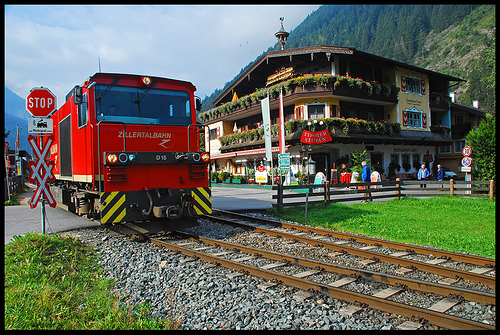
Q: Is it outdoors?
A: Yes, it is outdoors.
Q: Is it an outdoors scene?
A: Yes, it is outdoors.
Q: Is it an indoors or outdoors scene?
A: It is outdoors.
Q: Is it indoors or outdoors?
A: It is outdoors.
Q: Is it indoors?
A: No, it is outdoors.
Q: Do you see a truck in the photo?
A: No, there are no trucks.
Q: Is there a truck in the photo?
A: No, there are no trucks.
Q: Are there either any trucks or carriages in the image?
A: No, there are no trucks or carriages.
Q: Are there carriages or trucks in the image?
A: No, there are no trucks or carriages.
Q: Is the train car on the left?
A: Yes, the train car is on the left of the image.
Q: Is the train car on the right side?
A: No, the train car is on the left of the image.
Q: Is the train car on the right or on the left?
A: The train car is on the left of the image.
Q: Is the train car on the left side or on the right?
A: The train car is on the left of the image.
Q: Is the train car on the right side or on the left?
A: The train car is on the left of the image.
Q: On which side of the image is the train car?
A: The train car is on the left of the image.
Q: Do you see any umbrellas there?
A: No, there are no umbrellas.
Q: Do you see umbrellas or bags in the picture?
A: No, there are no umbrellas or bags.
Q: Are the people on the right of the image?
A: Yes, the people are on the right of the image.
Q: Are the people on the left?
A: No, the people are on the right of the image.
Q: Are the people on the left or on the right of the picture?
A: The people are on the right of the image.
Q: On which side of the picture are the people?
A: The people are on the right of the image.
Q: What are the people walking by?
A: The people are walking by the entrance.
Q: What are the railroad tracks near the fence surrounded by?
A: The railroad tracks are surrounded by the rocks.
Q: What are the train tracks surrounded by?
A: The railroad tracks are surrounded by the rocks.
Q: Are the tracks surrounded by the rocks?
A: Yes, the tracks are surrounded by the rocks.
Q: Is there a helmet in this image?
A: No, there are no helmets.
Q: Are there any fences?
A: Yes, there is a fence.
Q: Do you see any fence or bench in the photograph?
A: Yes, there is a fence.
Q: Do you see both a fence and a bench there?
A: No, there is a fence but no benches.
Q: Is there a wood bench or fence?
A: Yes, there is a wood fence.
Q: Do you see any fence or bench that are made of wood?
A: Yes, the fence is made of wood.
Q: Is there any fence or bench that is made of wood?
A: Yes, the fence is made of wood.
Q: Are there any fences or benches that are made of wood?
A: Yes, the fence is made of wood.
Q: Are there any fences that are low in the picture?
A: Yes, there is a low fence.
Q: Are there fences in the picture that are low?
A: Yes, there is a fence that is low.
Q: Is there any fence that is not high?
A: Yes, there is a low fence.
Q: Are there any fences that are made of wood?
A: Yes, there is a fence that is made of wood.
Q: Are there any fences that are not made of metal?
A: Yes, there is a fence that is made of wood.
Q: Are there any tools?
A: No, there are no tools.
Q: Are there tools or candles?
A: No, there are no tools or candles.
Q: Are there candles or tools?
A: No, there are no tools or candles.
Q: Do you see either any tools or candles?
A: No, there are no tools or candles.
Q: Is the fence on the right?
A: Yes, the fence is on the right of the image.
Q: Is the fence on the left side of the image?
A: No, the fence is on the right of the image.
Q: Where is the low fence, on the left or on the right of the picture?
A: The fence is on the right of the image.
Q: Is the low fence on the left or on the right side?
A: The fence is on the right of the image.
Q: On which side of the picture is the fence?
A: The fence is on the right of the image.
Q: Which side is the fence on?
A: The fence is on the right of the image.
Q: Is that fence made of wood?
A: Yes, the fence is made of wood.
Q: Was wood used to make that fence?
A: Yes, the fence is made of wood.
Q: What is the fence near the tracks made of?
A: The fence is made of wood.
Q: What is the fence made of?
A: The fence is made of wood.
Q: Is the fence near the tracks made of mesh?
A: No, the fence is made of wood.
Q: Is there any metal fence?
A: No, there is a fence but it is made of wood.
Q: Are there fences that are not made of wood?
A: No, there is a fence but it is made of wood.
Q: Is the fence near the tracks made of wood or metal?
A: The fence is made of wood.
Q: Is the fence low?
A: Yes, the fence is low.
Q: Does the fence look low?
A: Yes, the fence is low.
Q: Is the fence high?
A: No, the fence is low.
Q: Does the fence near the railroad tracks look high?
A: No, the fence is low.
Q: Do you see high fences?
A: No, there is a fence but it is low.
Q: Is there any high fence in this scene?
A: No, there is a fence but it is low.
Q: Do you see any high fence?
A: No, there is a fence but it is low.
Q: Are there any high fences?
A: No, there is a fence but it is low.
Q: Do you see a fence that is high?
A: No, there is a fence but it is low.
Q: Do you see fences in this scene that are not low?
A: No, there is a fence but it is low.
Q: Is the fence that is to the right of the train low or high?
A: The fence is low.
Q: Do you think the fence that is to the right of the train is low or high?
A: The fence is low.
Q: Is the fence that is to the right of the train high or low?
A: The fence is low.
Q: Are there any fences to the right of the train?
A: Yes, there is a fence to the right of the train.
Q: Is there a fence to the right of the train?
A: Yes, there is a fence to the right of the train.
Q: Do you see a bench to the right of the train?
A: No, there is a fence to the right of the train.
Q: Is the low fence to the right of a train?
A: Yes, the fence is to the right of a train.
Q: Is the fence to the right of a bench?
A: No, the fence is to the right of a train.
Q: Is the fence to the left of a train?
A: No, the fence is to the right of a train.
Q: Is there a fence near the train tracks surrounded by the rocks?
A: Yes, there is a fence near the tracks.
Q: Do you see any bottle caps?
A: No, there are no bottle caps.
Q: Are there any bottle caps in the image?
A: No, there are no bottle caps.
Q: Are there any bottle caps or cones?
A: No, there are no bottle caps or cones.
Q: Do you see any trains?
A: Yes, there is a train.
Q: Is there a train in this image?
A: Yes, there is a train.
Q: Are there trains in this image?
A: Yes, there is a train.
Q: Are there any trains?
A: Yes, there is a train.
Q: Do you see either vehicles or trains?
A: Yes, there is a train.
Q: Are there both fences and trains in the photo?
A: Yes, there are both a train and a fence.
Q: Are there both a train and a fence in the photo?
A: Yes, there are both a train and a fence.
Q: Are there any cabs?
A: No, there are no cabs.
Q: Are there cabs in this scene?
A: No, there are no cabs.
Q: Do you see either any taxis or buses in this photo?
A: No, there are no taxis or buses.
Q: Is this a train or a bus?
A: This is a train.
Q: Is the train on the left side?
A: Yes, the train is on the left of the image.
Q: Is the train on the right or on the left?
A: The train is on the left of the image.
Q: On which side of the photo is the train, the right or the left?
A: The train is on the left of the image.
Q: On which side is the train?
A: The train is on the left of the image.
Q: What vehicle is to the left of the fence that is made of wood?
A: The vehicle is a train.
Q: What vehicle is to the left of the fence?
A: The vehicle is a train.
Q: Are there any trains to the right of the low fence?
A: No, the train is to the left of the fence.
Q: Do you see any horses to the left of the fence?
A: No, there is a train to the left of the fence.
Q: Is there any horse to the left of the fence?
A: No, there is a train to the left of the fence.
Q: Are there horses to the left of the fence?
A: No, there is a train to the left of the fence.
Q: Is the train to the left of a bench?
A: No, the train is to the left of the fence.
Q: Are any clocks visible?
A: No, there are no clocks.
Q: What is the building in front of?
A: The building is in front of the hill.